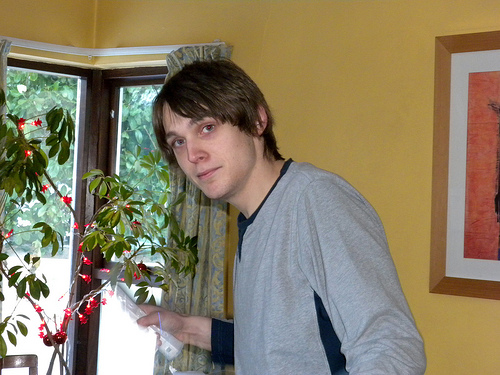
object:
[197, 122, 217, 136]
eyes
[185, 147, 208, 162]
nose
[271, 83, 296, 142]
wall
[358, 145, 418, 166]
wall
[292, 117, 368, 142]
wall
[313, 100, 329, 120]
paint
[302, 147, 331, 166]
walls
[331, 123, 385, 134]
walls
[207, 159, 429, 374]
shirt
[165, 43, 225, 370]
curtains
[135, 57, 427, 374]
man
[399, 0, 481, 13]
wall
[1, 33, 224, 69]
curtain rod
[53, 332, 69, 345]
berries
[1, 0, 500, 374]
background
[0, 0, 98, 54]
wall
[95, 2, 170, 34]
wall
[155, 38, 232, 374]
curtain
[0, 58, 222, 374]
window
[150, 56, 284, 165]
hair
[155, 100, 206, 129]
forehead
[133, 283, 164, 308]
leaves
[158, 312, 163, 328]
stripe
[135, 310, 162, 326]
thumb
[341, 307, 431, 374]
wrinkles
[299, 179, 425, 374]
sleeve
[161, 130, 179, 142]
eyebrow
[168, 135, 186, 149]
eye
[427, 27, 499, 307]
artwork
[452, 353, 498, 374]
wall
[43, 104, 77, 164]
leaves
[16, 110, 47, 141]
branch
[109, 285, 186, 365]
controller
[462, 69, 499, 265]
painting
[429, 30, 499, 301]
frame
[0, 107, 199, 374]
plant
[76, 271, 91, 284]
flowers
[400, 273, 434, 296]
walls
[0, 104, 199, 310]
tree branches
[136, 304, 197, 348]
hand